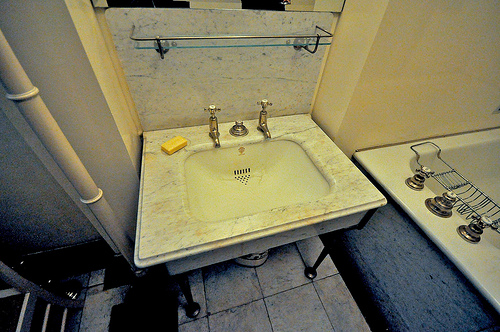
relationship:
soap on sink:
[162, 137, 188, 152] [133, 115, 386, 268]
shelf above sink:
[133, 28, 334, 57] [133, 115, 386, 268]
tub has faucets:
[360, 119, 499, 298] [407, 164, 493, 247]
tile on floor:
[205, 278, 335, 331] [85, 233, 379, 330]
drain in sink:
[232, 163, 256, 189] [133, 115, 386, 268]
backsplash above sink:
[105, 8, 336, 129] [133, 115, 386, 268]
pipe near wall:
[0, 37, 144, 279] [1, 1, 138, 265]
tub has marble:
[360, 119, 499, 298] [355, 212, 477, 327]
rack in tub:
[412, 144, 499, 218] [360, 119, 499, 298]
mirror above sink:
[98, 0, 344, 17] [133, 115, 386, 268]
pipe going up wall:
[0, 37, 144, 279] [1, 1, 138, 265]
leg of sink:
[302, 229, 353, 284] [133, 115, 386, 268]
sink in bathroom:
[133, 115, 386, 268] [2, 1, 496, 330]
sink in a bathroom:
[133, 115, 386, 268] [2, 1, 496, 330]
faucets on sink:
[199, 101, 277, 150] [133, 115, 386, 268]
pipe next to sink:
[0, 37, 144, 279] [133, 115, 386, 268]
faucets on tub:
[407, 164, 493, 247] [360, 119, 499, 298]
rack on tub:
[412, 144, 499, 218] [360, 119, 499, 298]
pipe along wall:
[0, 37, 144, 279] [1, 1, 138, 265]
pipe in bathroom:
[0, 37, 144, 279] [2, 1, 496, 330]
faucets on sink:
[407, 164, 493, 247] [133, 115, 386, 268]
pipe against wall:
[0, 37, 144, 279] [1, 1, 138, 265]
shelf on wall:
[133, 28, 334, 57] [1, 1, 138, 265]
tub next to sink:
[360, 119, 499, 298] [133, 115, 386, 268]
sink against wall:
[133, 115, 386, 268] [73, 3, 386, 323]